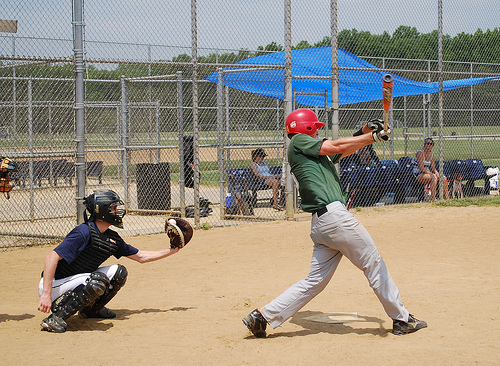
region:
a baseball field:
[0, 206, 498, 364]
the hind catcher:
[35, 185, 194, 330]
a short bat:
[380, 75, 393, 140]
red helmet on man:
[284, 105, 326, 135]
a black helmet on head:
[82, 188, 122, 217]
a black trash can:
[135, 161, 172, 208]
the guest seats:
[228, 156, 494, 201]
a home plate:
[299, 313, 364, 325]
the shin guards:
[53, 263, 126, 330]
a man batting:
[243, 68, 427, 336]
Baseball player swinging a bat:
[237, 70, 427, 342]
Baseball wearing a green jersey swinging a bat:
[240, 70, 429, 344]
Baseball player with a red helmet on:
[240, 71, 427, 343]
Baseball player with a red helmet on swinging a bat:
[239, 70, 429, 342]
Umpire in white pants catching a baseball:
[36, 186, 196, 332]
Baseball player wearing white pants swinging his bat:
[239, 73, 428, 342]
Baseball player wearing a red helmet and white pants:
[239, 70, 430, 345]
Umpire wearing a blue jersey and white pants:
[35, 188, 192, 334]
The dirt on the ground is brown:
[152, 301, 228, 356]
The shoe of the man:
[242, 298, 275, 338]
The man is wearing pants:
[258, 203, 420, 335]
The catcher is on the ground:
[20, 156, 201, 333]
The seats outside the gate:
[351, 153, 413, 202]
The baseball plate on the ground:
[301, 302, 368, 329]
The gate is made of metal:
[88, 35, 250, 167]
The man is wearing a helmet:
[73, 187, 135, 235]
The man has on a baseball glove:
[156, 210, 196, 253]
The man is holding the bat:
[370, 35, 400, 158]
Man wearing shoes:
[243, 302, 430, 337]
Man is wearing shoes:
[242, 302, 430, 340]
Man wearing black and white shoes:
[239, 306, 431, 344]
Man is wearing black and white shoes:
[237, 300, 429, 342]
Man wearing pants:
[241, 201, 416, 325]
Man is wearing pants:
[252, 195, 413, 327]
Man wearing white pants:
[250, 198, 411, 326]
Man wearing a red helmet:
[278, 102, 333, 139]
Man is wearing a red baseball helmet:
[279, 101, 344, 143]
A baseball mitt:
[164, 217, 194, 247]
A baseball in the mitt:
[169, 217, 176, 224]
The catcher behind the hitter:
[40, 188, 190, 334]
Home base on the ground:
[303, 304, 360, 328]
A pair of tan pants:
[263, 210, 405, 322]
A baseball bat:
[379, 72, 398, 137]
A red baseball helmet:
[285, 108, 326, 133]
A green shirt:
[285, 134, 345, 208]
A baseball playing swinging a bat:
[240, 75, 427, 340]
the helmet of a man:
[274, 102, 323, 144]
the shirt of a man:
[285, 132, 348, 213]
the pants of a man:
[253, 214, 412, 335]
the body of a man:
[289, 140, 339, 202]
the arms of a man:
[300, 126, 387, 163]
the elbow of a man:
[320, 131, 354, 163]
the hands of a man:
[365, 115, 393, 146]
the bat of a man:
[367, 61, 404, 153]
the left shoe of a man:
[227, 301, 275, 345]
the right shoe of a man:
[392, 309, 437, 339]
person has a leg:
[342, 236, 404, 316]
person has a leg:
[49, 271, 109, 320]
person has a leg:
[96, 266, 128, 311]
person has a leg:
[266, 176, 278, 201]